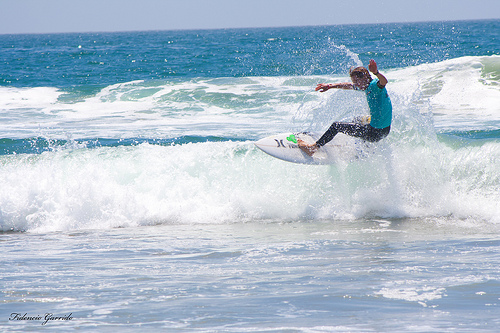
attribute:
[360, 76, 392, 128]
rashguard — blue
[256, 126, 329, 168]
surfboard — white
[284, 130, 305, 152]
sticker — green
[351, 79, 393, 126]
shirt — blue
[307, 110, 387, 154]
pants — black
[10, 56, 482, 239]
waves — white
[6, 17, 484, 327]
water — blue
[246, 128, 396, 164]
surfboard — white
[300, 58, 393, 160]
surfer — white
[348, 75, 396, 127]
shirt — blue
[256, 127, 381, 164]
board — white, pointed